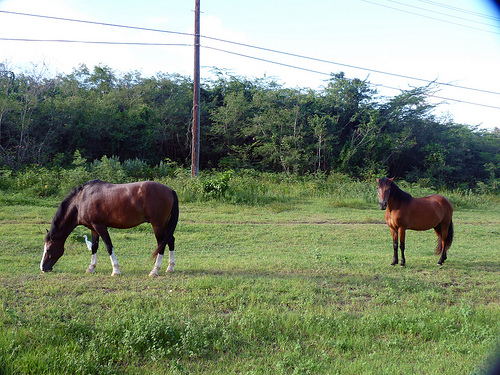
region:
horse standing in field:
[32, 185, 192, 285]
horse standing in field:
[375, 176, 454, 266]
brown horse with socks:
[38, 185, 179, 277]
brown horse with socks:
[371, 177, 453, 267]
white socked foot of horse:
[82, 253, 97, 270]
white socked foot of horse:
[108, 255, 119, 275]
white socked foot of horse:
[147, 251, 164, 279]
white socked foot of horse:
[167, 250, 174, 270]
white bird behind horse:
[80, 234, 91, 252]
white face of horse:
[37, 237, 49, 275]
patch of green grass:
[334, 330, 442, 372]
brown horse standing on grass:
[369, 171, 466, 266]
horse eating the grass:
[43, 172, 189, 278]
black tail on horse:
[170, 184, 183, 243]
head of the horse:
[32, 230, 67, 283]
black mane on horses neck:
[49, 178, 93, 223]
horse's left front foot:
[106, 248, 125, 277]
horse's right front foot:
[86, 236, 102, 278]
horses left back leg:
[148, 239, 163, 281]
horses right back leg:
[169, 239, 180, 279]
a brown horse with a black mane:
[363, 178, 462, 264]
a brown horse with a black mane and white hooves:
[40, 168, 180, 287]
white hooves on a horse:
[88, 246, 179, 282]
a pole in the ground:
[184, 2, 205, 192]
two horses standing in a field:
[35, 164, 475, 292]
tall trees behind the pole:
[2, 55, 497, 192]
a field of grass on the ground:
[1, 197, 496, 372]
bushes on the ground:
[2, 155, 492, 219]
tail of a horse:
[148, 192, 193, 262]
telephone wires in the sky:
[1, 3, 498, 127]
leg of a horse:
[80, 226, 101, 288]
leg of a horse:
[102, 222, 140, 282]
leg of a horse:
[137, 232, 175, 307]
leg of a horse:
[163, 219, 194, 287]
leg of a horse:
[375, 228, 403, 269]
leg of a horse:
[397, 232, 414, 267]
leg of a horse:
[420, 232, 467, 284]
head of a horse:
[10, 218, 87, 285]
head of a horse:
[363, 171, 415, 216]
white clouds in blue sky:
[21, 12, 53, 52]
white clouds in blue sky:
[31, 8, 98, 55]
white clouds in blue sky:
[112, 3, 177, 35]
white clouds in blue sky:
[218, 15, 285, 63]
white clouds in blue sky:
[287, 25, 384, 87]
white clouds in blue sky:
[408, 16, 472, 66]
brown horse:
[364, 163, 451, 264]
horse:
[18, 158, 190, 278]